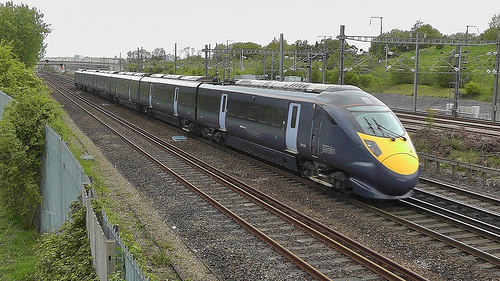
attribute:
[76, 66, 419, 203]
train — dark blue, long, black, yello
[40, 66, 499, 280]
tracks — brown, gray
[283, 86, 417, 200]
section — engineer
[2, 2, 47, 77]
tree — green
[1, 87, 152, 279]
fence — wooden, gray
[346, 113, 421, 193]
train nose — yellow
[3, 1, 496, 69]
sky — gray, white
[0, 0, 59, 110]
trees — green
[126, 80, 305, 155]
doors — white, gray